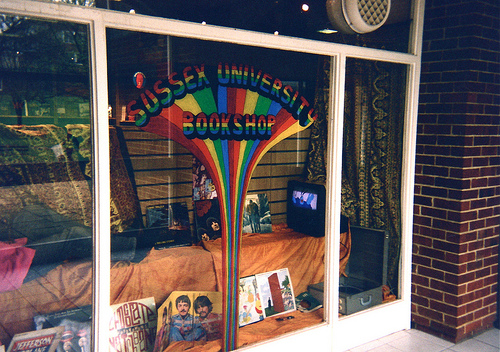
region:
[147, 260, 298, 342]
records in a window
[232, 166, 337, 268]
t.v. in store window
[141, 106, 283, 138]
rainbow letters that spell bookshop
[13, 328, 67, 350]
record of the band jefferson airplane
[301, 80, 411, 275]
curtains in a window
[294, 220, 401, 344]
gray box in window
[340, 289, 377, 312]
gray handle of a box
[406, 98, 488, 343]
red and white brick pillar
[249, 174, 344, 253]
t.v. tjhat is turned on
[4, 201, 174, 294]
person laying in store window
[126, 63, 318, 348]
the colorful design on the window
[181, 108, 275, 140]
the word BOOKSHOP on the window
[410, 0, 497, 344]
the bricks on the building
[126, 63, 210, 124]
the word SUSSEX on the window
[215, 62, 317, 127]
the word UNIVERSITY on the window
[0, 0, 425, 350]
the large window on the building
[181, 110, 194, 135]
the letter B on the window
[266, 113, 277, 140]
the letter P on the window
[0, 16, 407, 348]
the various contents in the window display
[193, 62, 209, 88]
the X on the window display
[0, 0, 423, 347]
showcase of store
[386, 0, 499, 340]
wall of building of brick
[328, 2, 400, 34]
a vent on top the window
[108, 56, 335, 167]
name of the book shop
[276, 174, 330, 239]
a screen of TV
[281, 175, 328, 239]
a black TV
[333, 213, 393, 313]
an open metal box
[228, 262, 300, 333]
an open book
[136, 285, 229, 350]
four men on book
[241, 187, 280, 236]
a couple on cover of book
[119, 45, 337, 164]
name of the bookstore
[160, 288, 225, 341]
beatles photo in window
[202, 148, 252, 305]
rainbow design on store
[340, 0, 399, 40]
airvent on store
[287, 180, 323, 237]
tv in the bookstore window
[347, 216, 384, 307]
empty suitcase in window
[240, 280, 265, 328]
winnie the pooh book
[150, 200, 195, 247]
albumn cover in window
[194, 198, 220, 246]
beatles albumn cover in window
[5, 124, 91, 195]
oriental rug in the window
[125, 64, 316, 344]
Rainbow bookshop sign.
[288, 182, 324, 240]
Old fashioned tv or monitor.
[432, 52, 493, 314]
Dark red multiple brick column.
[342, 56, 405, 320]
Large side picture window.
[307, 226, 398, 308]
Old timey record player.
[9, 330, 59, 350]
Jefferson airplane vinyl album.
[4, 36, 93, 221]
Reflections showing in a storefront window.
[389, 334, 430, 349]
Concrete tiles in front of a record store.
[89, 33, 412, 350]
White wooden frame encasing glass windows.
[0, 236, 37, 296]
Bright pink wrapping paper.